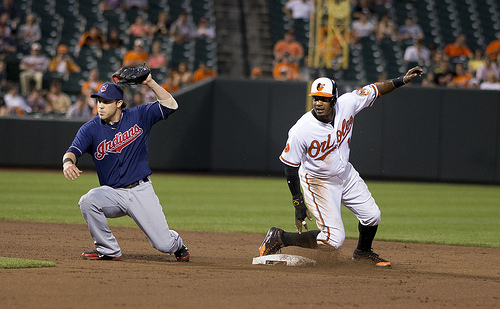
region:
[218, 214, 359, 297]
Base in a baseball game.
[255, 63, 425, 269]
Professional Orioles baseball player.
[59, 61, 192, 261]
Professional Indians baseball player.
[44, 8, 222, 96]
People wearing orange shirts.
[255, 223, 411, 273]
Pair of orange shoes.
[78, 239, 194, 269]
Pair of red shoes.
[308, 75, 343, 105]
White and orange hat.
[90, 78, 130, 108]
Blue and red hat.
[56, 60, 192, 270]
Person with baseball glove.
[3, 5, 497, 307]
Major league baseball game.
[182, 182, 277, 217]
well manicured ball park field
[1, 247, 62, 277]
portion of infield green mound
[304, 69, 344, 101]
white baseball cap with red and black symbol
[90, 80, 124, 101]
blue baseball cap with red and white symbol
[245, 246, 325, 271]
white mound at home plate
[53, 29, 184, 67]
spectators sitting in the stand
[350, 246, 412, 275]
black baseball shoes with orange tip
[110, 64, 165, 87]
black baseball gloves with orange marking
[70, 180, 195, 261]
man wearing gray baseball pants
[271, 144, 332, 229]
man wearing long sleeved black under shirt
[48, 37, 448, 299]
two players on the baseball field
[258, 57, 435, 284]
an Orioles baseball player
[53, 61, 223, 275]
an Indians baseball player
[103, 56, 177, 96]
a black baseball glove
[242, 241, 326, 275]
the second base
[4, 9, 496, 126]
fans in the crowd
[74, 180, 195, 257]
a pair of grey baseball pants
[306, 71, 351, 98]
a batter's helmet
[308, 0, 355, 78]
a yellow tower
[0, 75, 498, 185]
a fence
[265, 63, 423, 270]
Baseball player wearing Orioles uniform.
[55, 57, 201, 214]
Baseball player wearing Indians uniform.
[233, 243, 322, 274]
Base mat player in Orioles uniform is stepping on.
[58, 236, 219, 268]
Red and black sneakers of baseball player in Indians uniform.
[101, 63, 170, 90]
Baseball mitt being held by player in Indian's uniform.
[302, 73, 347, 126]
Head of baseball player in Orioles uniform.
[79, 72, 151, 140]
Head of baseball player in Indians uniform.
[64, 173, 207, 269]
Gray pants of player in Indians uniform.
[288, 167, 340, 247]
Red stripe on pants of player in white baseball uniform.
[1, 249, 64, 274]
Grass near player in gray baseball pants foot.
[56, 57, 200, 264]
Baseball player catching ball.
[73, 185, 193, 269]
Player wearing gray pants.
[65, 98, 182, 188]
Player wearing navy blue shirt.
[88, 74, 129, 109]
Player wearing navy blue cap.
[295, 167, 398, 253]
Player wearing white pants.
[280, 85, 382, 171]
Player wearing white shirt.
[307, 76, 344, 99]
Player wearing white cap.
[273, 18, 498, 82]
Fans wearing orange shirts.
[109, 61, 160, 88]
Player wearing baseball mitt.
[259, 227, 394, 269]
Player wearing black and orange shoes.